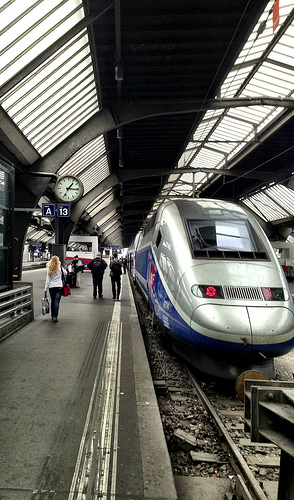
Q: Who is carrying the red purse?
A: Blonde woman.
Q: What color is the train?
A: Blue and silver.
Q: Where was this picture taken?
A: Train station.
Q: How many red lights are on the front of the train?
A: Two.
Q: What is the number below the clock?
A: 13.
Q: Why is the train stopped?
A: For passengers.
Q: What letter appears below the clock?
A: A.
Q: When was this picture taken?
A: 1:15.